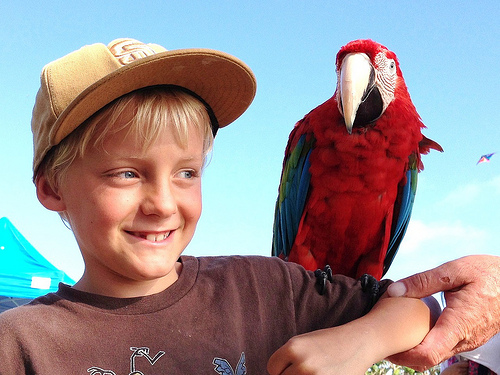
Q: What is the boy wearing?
A: A cap.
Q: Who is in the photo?
A: A boy.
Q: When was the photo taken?
A: Daytime.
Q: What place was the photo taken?
A: Outdoors.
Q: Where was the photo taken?
A: At an event.